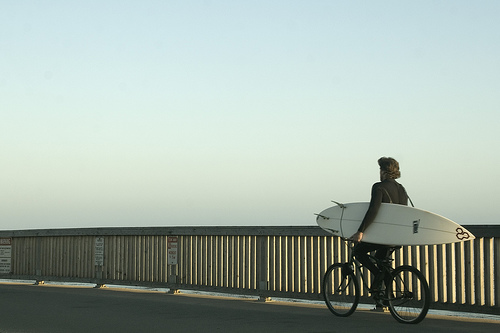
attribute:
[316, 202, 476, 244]
surfboard — white, wide, pointy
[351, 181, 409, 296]
wetsuit — black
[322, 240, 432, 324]
bike — black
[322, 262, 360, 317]
wheel — back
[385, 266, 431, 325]
wheel — back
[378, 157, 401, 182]
hair — coiled, shaggy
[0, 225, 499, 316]
fence — wooden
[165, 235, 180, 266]
sign — red, white, warning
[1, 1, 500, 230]
sky — blue, cloudless, light blue